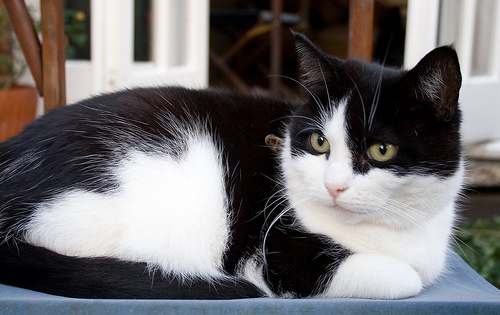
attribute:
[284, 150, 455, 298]
hair — soft, white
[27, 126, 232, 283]
hair — soft, white, large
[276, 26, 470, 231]
face — black, white, cat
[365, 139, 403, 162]
eye — yellow, black, lime green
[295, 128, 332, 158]
eye — yellow, black, lime green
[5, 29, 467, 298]
cat — calm, curious, looking, black, white, lying down, curled up, laying down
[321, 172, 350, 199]
nose — pink, small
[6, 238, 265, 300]
tail — black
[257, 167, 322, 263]
whiskers — white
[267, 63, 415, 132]
whiskers — white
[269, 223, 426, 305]
paw — black, white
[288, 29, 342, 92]
ear — black, white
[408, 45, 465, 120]
ear — black, white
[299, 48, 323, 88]
hairs — white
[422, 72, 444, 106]
hairs — white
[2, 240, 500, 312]
chair — blue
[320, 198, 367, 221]
mouth — white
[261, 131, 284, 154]
collar — sticking out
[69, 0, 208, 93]
door — white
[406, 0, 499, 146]
door — white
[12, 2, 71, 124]
beam — wooden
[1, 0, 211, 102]
wall — white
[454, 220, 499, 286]
foilag — green